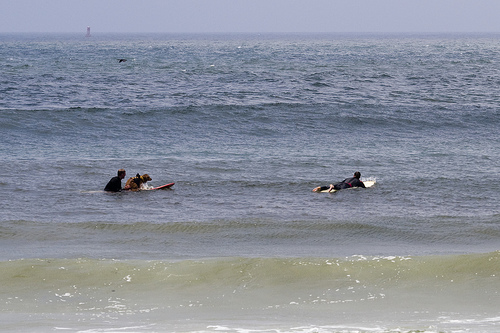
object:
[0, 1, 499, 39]
sky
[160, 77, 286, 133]
water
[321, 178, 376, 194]
surfboard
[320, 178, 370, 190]
wetsuit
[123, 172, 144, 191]
dog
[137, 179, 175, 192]
surfboard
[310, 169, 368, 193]
man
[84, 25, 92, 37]
floater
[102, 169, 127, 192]
man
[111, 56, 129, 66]
bird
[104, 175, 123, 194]
black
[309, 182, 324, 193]
feet